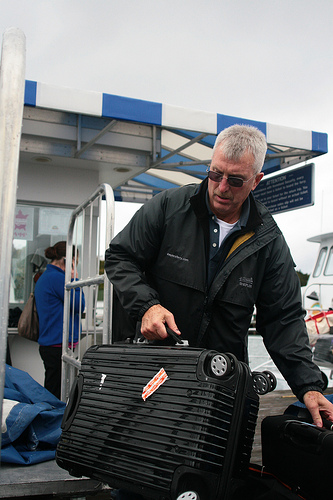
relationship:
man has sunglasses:
[155, 115, 277, 279] [195, 160, 262, 205]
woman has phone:
[27, 228, 78, 390] [57, 254, 82, 279]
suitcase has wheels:
[34, 338, 262, 491] [184, 350, 274, 405]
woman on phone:
[27, 228, 78, 390] [57, 254, 82, 279]